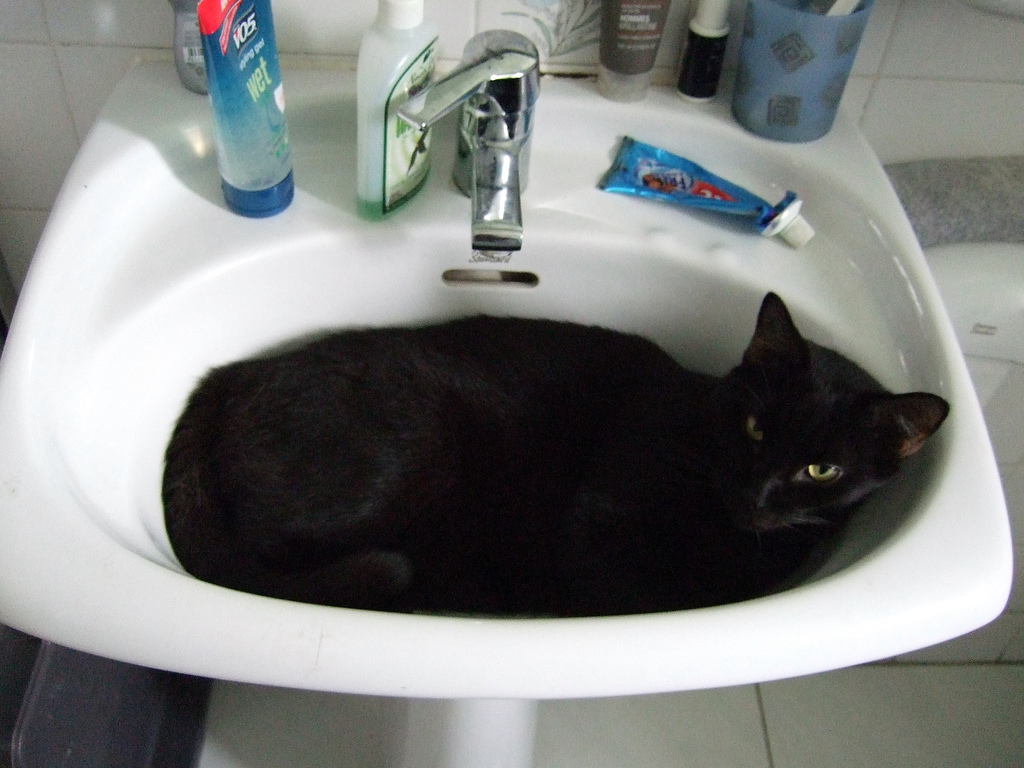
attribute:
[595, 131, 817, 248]
toothpaste — small, flattened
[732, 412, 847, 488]
eyes — set